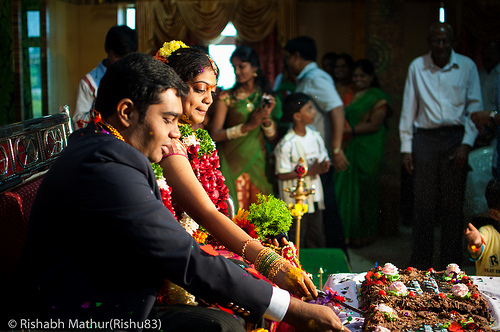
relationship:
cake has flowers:
[361, 261, 499, 332] [446, 259, 469, 298]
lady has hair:
[158, 37, 318, 304] [166, 49, 221, 81]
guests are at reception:
[74, 23, 499, 277] [1, 0, 498, 330]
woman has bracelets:
[158, 37, 318, 304] [241, 237, 286, 286]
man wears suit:
[1, 55, 292, 313] [22, 128, 274, 332]